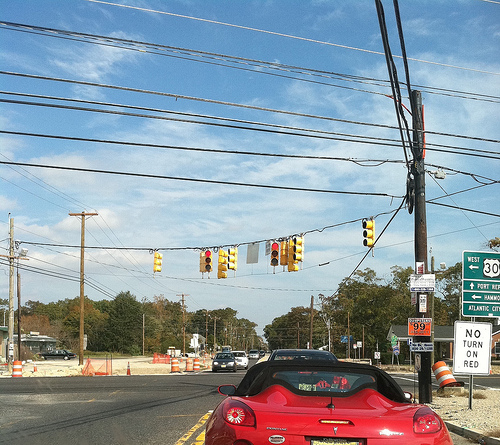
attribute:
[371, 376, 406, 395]
corvette — red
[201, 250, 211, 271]
traffic light — yellow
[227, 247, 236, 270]
traffic light — yellow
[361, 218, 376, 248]
traffic light — yellow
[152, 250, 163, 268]
traffic light — yellow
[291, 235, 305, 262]
traffic light — yellow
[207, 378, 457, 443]
corvette — red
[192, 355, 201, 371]
cone — orange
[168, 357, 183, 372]
cone — orange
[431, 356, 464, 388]
cone — orange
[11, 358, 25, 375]
cone — orange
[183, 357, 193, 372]
cone — orange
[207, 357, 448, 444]
corvette — red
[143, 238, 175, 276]
traffic light — yellow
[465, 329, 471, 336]
letter — black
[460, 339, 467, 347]
letter — black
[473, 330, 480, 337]
letter — black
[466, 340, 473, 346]
letter — black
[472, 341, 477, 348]
letter — black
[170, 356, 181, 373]
cone — orange, white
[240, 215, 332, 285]
light — yellow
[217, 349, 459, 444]
corvette — red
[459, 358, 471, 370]
letter — black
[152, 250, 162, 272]
traffic light — yellow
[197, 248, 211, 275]
traffic light — yellow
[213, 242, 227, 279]
traffic light — yellow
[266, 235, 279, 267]
traffic light — yellow